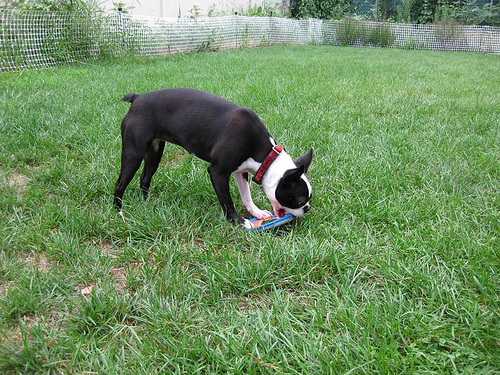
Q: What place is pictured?
A: It is a backyard.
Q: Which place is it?
A: It is a backyard.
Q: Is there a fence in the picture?
A: Yes, there is a fence.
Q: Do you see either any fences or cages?
A: Yes, there is a fence.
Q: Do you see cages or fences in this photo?
A: Yes, there is a fence.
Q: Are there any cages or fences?
A: Yes, there is a fence.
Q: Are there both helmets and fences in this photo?
A: No, there is a fence but no helmets.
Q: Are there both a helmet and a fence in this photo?
A: No, there is a fence but no helmets.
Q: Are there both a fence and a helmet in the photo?
A: No, there is a fence but no helmets.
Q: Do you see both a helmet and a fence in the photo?
A: No, there is a fence but no helmets.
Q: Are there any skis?
A: No, there are no skis.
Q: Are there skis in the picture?
A: No, there are no skis.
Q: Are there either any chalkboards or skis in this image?
A: No, there are no skis or chalkboards.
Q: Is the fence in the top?
A: Yes, the fence is in the top of the image.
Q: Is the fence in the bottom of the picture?
A: No, the fence is in the top of the image.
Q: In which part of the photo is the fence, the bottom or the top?
A: The fence is in the top of the image.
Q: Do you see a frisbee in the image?
A: Yes, there is a frisbee.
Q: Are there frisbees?
A: Yes, there is a frisbee.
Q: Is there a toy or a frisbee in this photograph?
A: Yes, there is a frisbee.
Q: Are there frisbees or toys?
A: Yes, there is a frisbee.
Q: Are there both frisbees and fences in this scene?
A: Yes, there are both a frisbee and a fence.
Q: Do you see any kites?
A: No, there are no kites.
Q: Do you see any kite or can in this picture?
A: No, there are no kites or cans.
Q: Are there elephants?
A: No, there are no elephants.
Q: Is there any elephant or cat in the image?
A: No, there are no elephants or cats.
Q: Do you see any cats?
A: No, there are no cats.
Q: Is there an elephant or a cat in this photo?
A: No, there are no cats or elephants.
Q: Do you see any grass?
A: Yes, there is grass.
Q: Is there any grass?
A: Yes, there is grass.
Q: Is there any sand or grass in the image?
A: Yes, there is grass.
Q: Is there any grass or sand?
A: Yes, there is grass.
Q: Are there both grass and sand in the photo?
A: No, there is grass but no sand.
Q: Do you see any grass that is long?
A: Yes, there is long grass.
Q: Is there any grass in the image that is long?
A: Yes, there is grass that is long.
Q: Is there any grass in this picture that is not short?
A: Yes, there is long grass.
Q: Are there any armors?
A: No, there are no armors.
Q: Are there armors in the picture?
A: No, there are no armors.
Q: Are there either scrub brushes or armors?
A: No, there are no armors or scrub brushes.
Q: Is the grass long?
A: Yes, the grass is long.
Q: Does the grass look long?
A: Yes, the grass is long.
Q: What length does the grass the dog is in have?
A: The grass has long length.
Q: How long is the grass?
A: The grass is long.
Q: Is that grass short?
A: No, the grass is long.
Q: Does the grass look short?
A: No, the grass is long.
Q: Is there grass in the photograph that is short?
A: No, there is grass but it is long.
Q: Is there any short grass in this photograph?
A: No, there is grass but it is long.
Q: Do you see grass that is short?
A: No, there is grass but it is long.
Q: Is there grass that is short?
A: No, there is grass but it is long.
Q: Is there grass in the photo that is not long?
A: No, there is grass but it is long.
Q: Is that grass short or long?
A: The grass is long.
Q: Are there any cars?
A: No, there are no cars.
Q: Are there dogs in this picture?
A: Yes, there is a dog.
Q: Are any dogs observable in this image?
A: Yes, there is a dog.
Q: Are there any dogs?
A: Yes, there is a dog.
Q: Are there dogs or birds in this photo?
A: Yes, there is a dog.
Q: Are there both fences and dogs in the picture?
A: Yes, there are both a dog and a fence.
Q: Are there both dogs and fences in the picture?
A: Yes, there are both a dog and a fence.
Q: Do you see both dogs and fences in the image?
A: Yes, there are both a dog and a fence.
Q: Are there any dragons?
A: No, there are no dragons.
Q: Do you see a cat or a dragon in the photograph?
A: No, there are no dragons or cats.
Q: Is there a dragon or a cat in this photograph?
A: No, there are no dragons or cats.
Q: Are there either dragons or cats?
A: No, there are no dragons or cats.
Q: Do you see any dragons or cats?
A: No, there are no dragons or cats.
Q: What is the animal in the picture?
A: The animal is a dog.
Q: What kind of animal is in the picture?
A: The animal is a dog.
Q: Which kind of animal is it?
A: The animal is a dog.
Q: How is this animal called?
A: This is a dog.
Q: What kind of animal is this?
A: This is a dog.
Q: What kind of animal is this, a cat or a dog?
A: This is a dog.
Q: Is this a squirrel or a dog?
A: This is a dog.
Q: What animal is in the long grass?
A: The dog is in the grass.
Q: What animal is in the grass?
A: The dog is in the grass.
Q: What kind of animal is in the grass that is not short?
A: The animal is a dog.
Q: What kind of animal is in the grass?
A: The animal is a dog.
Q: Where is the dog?
A: The dog is in the grass.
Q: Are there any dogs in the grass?
A: Yes, there is a dog in the grass.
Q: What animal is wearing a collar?
A: The dog is wearing a collar.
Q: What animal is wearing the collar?
A: The dog is wearing a collar.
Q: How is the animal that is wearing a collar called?
A: The animal is a dog.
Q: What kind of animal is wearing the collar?
A: The animal is a dog.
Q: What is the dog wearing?
A: The dog is wearing a collar.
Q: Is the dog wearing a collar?
A: Yes, the dog is wearing a collar.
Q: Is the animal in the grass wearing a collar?
A: Yes, the dog is wearing a collar.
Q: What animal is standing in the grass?
A: The dog is standing in the grass.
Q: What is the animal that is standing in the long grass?
A: The animal is a dog.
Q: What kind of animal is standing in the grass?
A: The animal is a dog.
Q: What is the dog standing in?
A: The dog is standing in the grass.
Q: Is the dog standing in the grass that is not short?
A: Yes, the dog is standing in the grass.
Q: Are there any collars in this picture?
A: Yes, there is a collar.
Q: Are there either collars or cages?
A: Yes, there is a collar.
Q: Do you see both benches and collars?
A: No, there is a collar but no benches.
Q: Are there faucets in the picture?
A: No, there are no faucets.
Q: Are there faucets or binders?
A: No, there are no faucets or binders.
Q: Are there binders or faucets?
A: No, there are no faucets or binders.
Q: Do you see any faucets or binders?
A: No, there are no faucets or binders.